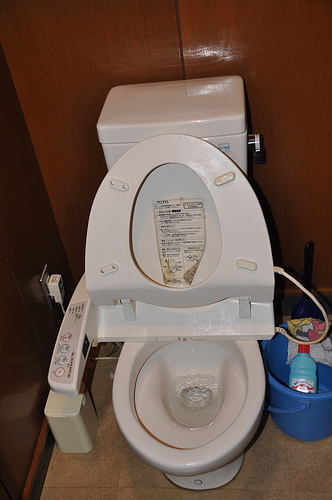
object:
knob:
[250, 128, 268, 158]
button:
[192, 478, 204, 486]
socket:
[46, 268, 67, 302]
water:
[170, 371, 224, 427]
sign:
[153, 198, 206, 288]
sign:
[53, 341, 77, 356]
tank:
[103, 89, 253, 145]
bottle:
[287, 341, 318, 393]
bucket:
[260, 315, 330, 444]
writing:
[65, 298, 84, 317]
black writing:
[68, 303, 84, 321]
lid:
[81, 129, 280, 340]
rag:
[286, 316, 331, 363]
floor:
[240, 442, 327, 497]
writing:
[152, 200, 204, 233]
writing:
[158, 217, 192, 223]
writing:
[182, 238, 204, 243]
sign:
[67, 303, 83, 319]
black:
[154, 190, 203, 280]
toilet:
[87, 148, 267, 406]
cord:
[273, 269, 324, 346]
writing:
[158, 195, 202, 276]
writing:
[150, 198, 205, 281]